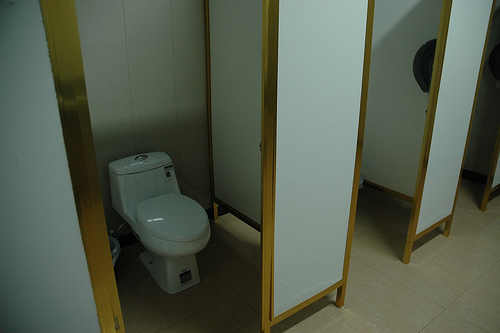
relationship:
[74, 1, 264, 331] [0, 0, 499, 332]
stall inside public bathroom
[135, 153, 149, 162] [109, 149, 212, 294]
flush button on top of toilet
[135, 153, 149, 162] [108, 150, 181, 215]
flush button on top of toilet tank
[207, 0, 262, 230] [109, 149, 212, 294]
wall to right of toilet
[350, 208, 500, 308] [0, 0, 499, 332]
tile inside public bathroom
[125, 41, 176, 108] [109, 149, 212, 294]
tile behind toilet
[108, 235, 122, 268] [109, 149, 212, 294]
garbage can near toilet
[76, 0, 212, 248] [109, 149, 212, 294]
wall behind toilet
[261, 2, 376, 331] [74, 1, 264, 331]
wall part of stall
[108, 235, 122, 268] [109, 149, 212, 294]
garbage can next to toilet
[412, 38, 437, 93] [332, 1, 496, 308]
paper dispenser inside stall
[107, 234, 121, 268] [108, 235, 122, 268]
bag inside garbage can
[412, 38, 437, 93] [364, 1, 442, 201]
paper dispenser attached to wall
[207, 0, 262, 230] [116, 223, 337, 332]
wall casting shadow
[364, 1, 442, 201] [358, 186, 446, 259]
wall casting shadow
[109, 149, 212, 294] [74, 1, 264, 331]
toilet inside stall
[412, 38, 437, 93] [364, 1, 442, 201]
paper dispenser hanging on wall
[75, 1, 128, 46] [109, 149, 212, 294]
tile behind toilet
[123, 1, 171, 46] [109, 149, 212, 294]
tile behind toilet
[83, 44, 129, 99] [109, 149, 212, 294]
tile behind toilet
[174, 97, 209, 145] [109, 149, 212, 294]
tile behind toilet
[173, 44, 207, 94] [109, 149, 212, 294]
tile behind toilet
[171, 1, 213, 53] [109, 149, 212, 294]
tile behind toilet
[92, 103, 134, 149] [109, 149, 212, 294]
tile behind toilet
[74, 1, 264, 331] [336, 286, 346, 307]
stall has leg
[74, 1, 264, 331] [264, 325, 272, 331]
stall has leg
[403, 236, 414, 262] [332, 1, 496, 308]
leg under stall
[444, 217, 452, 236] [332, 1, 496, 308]
leg under stall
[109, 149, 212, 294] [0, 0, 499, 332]
toilet inside public bathroom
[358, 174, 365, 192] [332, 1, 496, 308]
garbage can inside stall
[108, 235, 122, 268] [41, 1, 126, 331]
garbage can behind trim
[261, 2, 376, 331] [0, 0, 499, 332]
wall inside public bathroom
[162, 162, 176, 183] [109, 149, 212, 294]
label attached to toilet